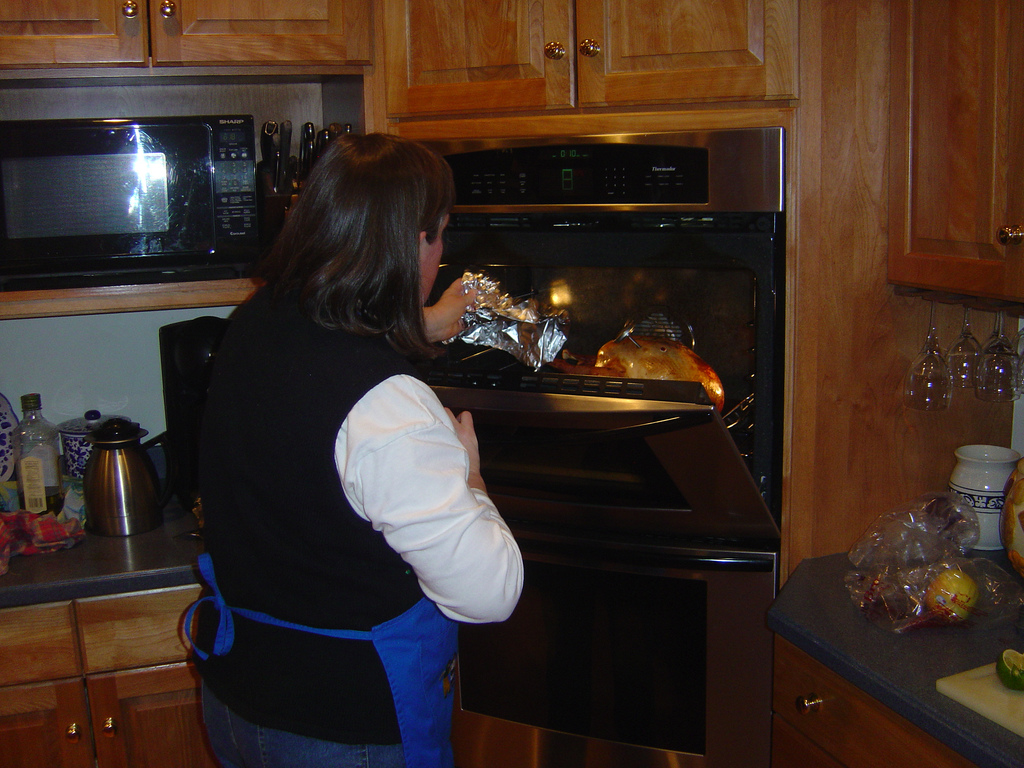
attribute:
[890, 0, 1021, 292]
cabinet — wooden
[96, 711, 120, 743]
handle — round